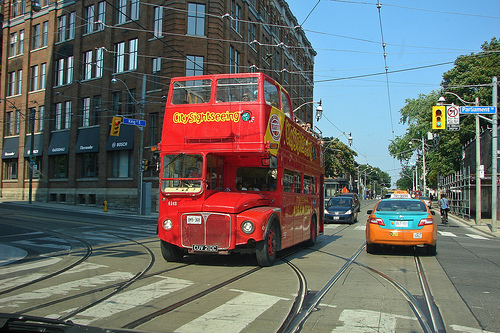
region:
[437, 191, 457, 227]
The person riding a bike.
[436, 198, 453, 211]
The blue shirt the person on the bike is wearing.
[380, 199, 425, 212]
The back window of the orange taxi.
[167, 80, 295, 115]
The windows on the upper deck of the bus.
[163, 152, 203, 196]
The front window of the bus on the lower level.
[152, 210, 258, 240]
The headlights of the double leveled bus.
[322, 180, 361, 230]
The two cars behind the red bus.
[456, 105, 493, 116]
The blue street sign on the right.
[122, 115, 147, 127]
The blue street sign on the left.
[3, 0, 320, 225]
The tall brown building.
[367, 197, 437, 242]
The orange and blue taxi.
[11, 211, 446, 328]
The street railing tracks on the ground.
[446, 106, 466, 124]
The white street sign with an arrow on it on the right.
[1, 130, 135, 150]
The black canopies over the windows of the brown building.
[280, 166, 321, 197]
The side windows on the lower level of the bus.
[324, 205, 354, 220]
The headlights on the black car behind the bus.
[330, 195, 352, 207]
The front window of the black car behind the bus.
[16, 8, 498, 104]
The wires above the traffic on the street.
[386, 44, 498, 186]
The trees lining the right side of the street.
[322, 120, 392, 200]
The trees lining the left side of the street.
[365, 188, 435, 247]
The orange and light blue taxi.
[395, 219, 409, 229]
The license plate of the taxi.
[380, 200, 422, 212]
The back window of the taxi.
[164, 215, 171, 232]
The left headlight of the double deck bus.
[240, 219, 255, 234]
The right headlight of the double deck bus.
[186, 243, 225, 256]
The black license plate of the double deck bus.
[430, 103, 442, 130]
The traffic light with the green light.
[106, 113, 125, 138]
The traffic light with the red light.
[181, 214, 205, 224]
The white license plate on the double deck bus.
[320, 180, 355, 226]
The black car behind the double deck bus.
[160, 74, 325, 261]
red double-decker bus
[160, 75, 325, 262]
bright red tour bus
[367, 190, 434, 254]
orange and blue taxi cab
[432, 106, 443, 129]
stop light showing green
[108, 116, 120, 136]
stop light showing red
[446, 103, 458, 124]
no left turns sign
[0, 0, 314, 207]
large brick building on the far corner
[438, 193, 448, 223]
person in a blue shirt on a bike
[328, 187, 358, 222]
cars directly behind the bus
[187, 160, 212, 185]
tour bus driver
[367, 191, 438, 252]
Blue and orange taxi cab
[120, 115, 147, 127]
Street sign attached utility wires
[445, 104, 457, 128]
No left turn sign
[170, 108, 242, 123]
Company logo on the front of a passenger bus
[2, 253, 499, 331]
Crosswalk painted on the street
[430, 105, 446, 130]
Traffic light at the intersection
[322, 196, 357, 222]
Black car traveling down the street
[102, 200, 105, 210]
Fire hydrant on the sidewalk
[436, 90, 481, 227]
Streetlight anchored to the sidewalk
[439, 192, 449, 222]
Person riding a bicycle in the street